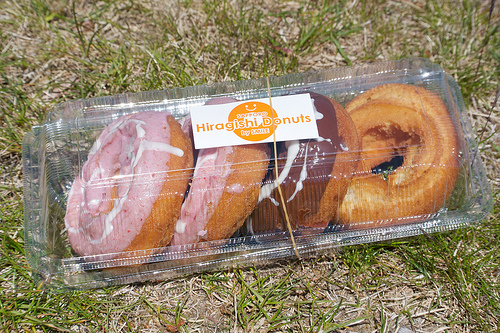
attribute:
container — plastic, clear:
[24, 59, 489, 295]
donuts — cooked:
[65, 84, 455, 265]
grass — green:
[232, 274, 334, 324]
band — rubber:
[262, 140, 300, 226]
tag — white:
[187, 85, 327, 152]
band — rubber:
[267, 140, 288, 197]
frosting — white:
[278, 171, 286, 180]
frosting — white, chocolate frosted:
[258, 183, 273, 198]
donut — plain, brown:
[331, 79, 470, 237]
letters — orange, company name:
[189, 107, 319, 134]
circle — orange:
[228, 99, 279, 139]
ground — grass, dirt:
[16, 11, 395, 43]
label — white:
[190, 90, 320, 160]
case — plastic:
[18, 65, 497, 296]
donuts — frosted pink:
[68, 90, 457, 250]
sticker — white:
[185, 90, 321, 152]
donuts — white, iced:
[57, 88, 271, 288]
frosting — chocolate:
[260, 202, 299, 232]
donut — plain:
[329, 85, 464, 223]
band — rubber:
[261, 133, 296, 210]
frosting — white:
[264, 182, 269, 199]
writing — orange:
[192, 112, 317, 128]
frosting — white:
[62, 115, 185, 245]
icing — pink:
[63, 105, 172, 262]